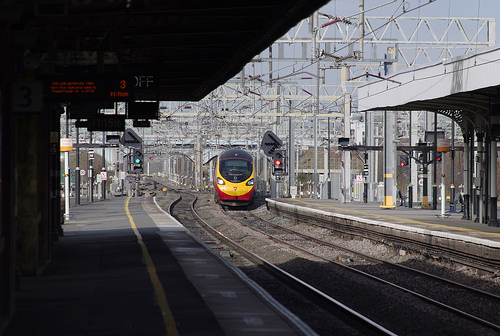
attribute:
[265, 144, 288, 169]
light — red, green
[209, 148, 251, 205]
train — red, arriving, yellow, moving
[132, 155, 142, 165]
light — green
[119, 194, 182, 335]
line — thick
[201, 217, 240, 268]
dirt — brown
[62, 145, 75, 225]
post — gray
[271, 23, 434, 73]
bars — steel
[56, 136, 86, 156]
sign — red, orange, white, hanging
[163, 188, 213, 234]
track — trainless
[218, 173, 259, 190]
headlights — here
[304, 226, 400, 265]
rail — rocks, gray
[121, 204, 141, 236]
lane — yellow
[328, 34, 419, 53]
sky — dull